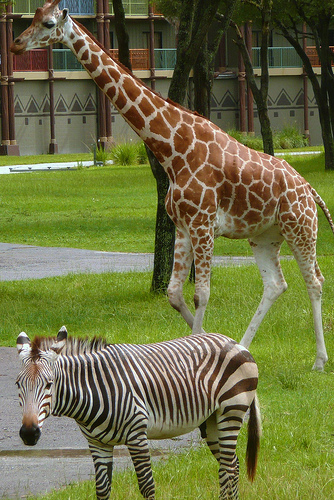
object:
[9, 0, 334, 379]
giraffe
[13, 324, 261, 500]
zebra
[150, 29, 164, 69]
door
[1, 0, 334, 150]
building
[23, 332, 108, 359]
mane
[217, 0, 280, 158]
tree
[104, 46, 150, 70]
railing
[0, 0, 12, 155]
pole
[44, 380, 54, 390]
eye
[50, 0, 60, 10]
horn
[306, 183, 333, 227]
tail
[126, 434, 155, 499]
leg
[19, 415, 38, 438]
nose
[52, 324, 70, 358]
ear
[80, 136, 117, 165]
plant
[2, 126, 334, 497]
grass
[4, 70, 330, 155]
wall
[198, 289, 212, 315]
knee